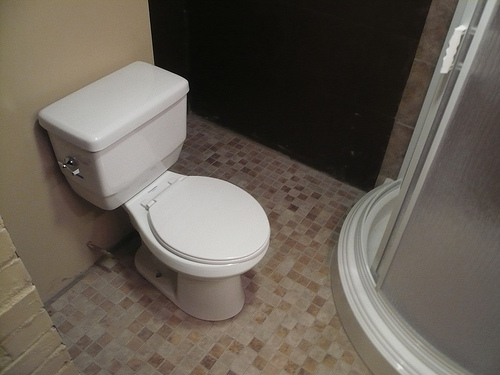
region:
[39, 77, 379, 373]
The floor is tiled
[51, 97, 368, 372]
The tiles are small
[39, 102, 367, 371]
The tiles are brown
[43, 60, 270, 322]
The toilet is white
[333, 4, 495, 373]
The shower is white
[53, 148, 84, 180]
The toilet handle is silver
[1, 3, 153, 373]
The wall is beige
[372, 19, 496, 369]
The shower door is cloudy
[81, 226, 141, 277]
Brown pipes underneath the toilet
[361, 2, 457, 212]
Brown tile on the wall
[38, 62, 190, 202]
water tank for the toilet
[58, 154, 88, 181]
handle to flush the toilet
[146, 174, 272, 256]
lid to close the hole in the toilet bowl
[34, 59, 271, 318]
toilet where human fecal matter is disposed of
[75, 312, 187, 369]
tile grounds are easier to manage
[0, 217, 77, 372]
brick wall to enclose the bathroom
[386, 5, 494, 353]
shower wall for showering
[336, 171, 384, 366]
shower floor to keep water in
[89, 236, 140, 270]
pipe leading to toilet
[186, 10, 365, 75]
dark ominous wall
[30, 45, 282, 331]
a toilet in the bathroom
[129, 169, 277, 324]
a lid over the toilet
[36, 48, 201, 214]
the tank of a toilet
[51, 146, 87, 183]
a handle on a tank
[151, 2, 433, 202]
a black door of a bathroom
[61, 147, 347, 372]
floor is color light and dark brown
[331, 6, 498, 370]
a cabinet of a shower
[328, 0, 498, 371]
cabinet is color white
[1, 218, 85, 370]
a wall of brick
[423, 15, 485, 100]
a white handle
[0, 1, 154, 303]
beige wall in bathroom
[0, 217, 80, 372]
beige painted brick wall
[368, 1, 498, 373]
glass shower door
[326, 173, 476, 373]
white shower base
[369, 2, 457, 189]
ceramic tiles on wall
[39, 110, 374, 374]
ceramic tiles on bathroom floor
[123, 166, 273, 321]
white ceramic toilet bowl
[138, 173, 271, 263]
white toilet seat and cover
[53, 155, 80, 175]
shiny grey metal toilet handle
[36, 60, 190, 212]
white toilet tank and lid